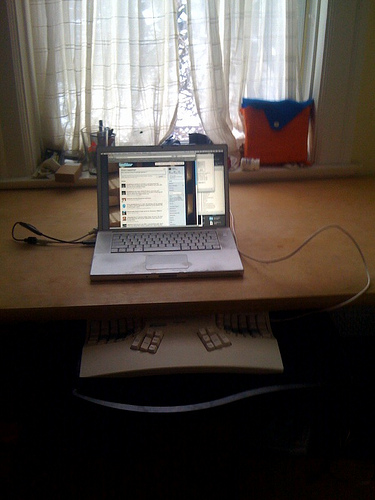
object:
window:
[17, 2, 333, 145]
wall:
[330, 1, 375, 176]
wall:
[0, 0, 34, 154]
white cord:
[266, 242, 307, 264]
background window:
[13, 0, 332, 170]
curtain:
[17, 0, 319, 180]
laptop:
[74, 134, 270, 308]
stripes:
[39, 81, 310, 94]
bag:
[239, 96, 314, 166]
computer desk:
[2, 176, 375, 321]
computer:
[85, 133, 246, 277]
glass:
[80, 125, 103, 158]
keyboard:
[78, 319, 283, 376]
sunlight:
[82, 43, 208, 126]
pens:
[94, 121, 114, 150]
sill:
[31, 127, 306, 181]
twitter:
[117, 164, 187, 224]